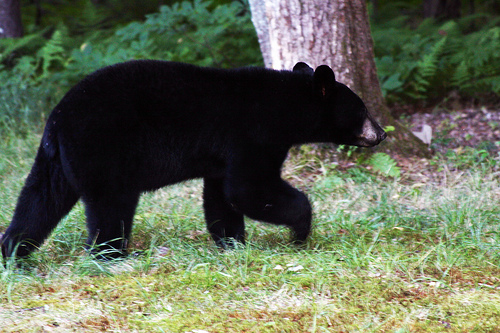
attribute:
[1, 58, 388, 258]
bear — black